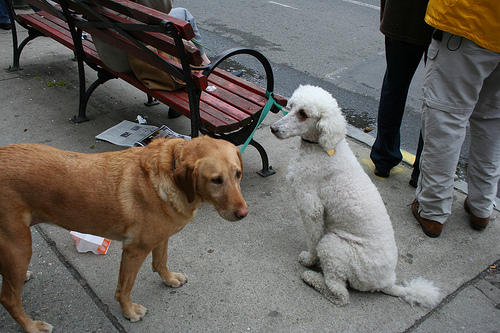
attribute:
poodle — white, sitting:
[269, 84, 440, 309]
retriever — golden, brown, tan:
[0, 135, 249, 332]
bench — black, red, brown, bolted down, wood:
[0, 0, 288, 179]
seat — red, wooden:
[18, 9, 287, 129]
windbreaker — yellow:
[425, 0, 498, 54]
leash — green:
[240, 89, 289, 153]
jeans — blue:
[368, 36, 431, 178]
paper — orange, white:
[70, 230, 112, 255]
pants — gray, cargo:
[415, 27, 500, 224]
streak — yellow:
[365, 150, 416, 179]